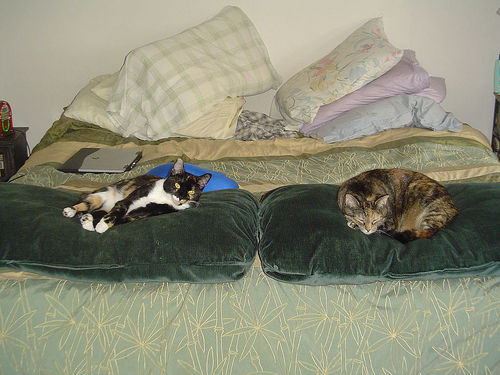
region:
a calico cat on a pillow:
[318, 158, 465, 248]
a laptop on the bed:
[58, 139, 145, 186]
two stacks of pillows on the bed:
[79, 5, 496, 160]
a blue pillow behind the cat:
[111, 145, 243, 219]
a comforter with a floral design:
[161, 293, 372, 371]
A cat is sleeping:
[330, 160, 462, 257]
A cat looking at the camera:
[64, 149, 224, 245]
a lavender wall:
[11, 12, 101, 79]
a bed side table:
[0, 97, 37, 181]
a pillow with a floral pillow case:
[276, 28, 387, 115]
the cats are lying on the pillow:
[27, 114, 484, 364]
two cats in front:
[21, 112, 456, 312]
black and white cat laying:
[45, 150, 217, 242]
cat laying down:
[80, 148, 202, 238]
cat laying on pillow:
[77, 124, 268, 259]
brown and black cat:
[340, 144, 457, 286]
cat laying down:
[265, 151, 425, 309]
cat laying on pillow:
[360, 137, 451, 248]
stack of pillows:
[250, 11, 445, 173]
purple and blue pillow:
[301, 30, 445, 148]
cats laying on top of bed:
[71, 37, 445, 267]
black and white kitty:
[98, 157, 208, 248]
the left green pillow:
[0, 149, 252, 284]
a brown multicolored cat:
[341, 160, 460, 245]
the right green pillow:
[256, 152, 499, 273]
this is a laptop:
[60, 134, 145, 179]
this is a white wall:
[21, 77, 55, 105]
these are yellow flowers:
[214, 284, 337, 351]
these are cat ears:
[331, 185, 401, 210]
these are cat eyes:
[171, 180, 205, 197]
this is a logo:
[82, 149, 110, 166]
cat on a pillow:
[325, 149, 438, 240]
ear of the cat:
[334, 179, 365, 216]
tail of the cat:
[418, 191, 475, 248]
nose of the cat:
[357, 221, 381, 241]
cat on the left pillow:
[56, 145, 221, 266]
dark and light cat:
[83, 143, 232, 230]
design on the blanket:
[161, 285, 297, 342]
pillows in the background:
[153, 14, 410, 134]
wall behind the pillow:
[18, 10, 90, 55]